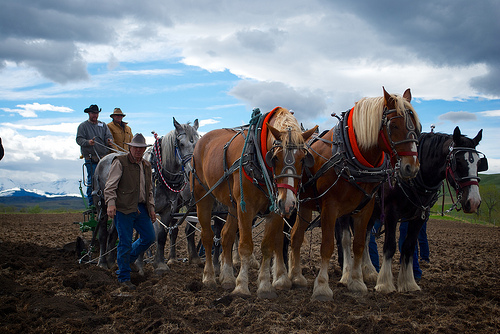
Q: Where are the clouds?
A: Sky.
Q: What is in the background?
A: Hills.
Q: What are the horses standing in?
A: Dirt.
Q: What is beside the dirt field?
A: Grass.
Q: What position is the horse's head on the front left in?
A: Down.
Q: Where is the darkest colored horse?
A: Front right.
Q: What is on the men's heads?
A: Hats.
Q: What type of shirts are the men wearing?
A: Long sleeved.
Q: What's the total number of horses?
A: 4.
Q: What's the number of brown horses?
A: 2.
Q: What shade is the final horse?
A: Grey.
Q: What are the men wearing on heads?
A: Cowboy hats.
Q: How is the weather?
A: Overcast.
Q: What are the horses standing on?
A: Dirt.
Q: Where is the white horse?
A: Closest to the men.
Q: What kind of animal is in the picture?
A: Horses.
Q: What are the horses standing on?
A: A dirt field.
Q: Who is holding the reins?
A: A man.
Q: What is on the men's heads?
A: Hats.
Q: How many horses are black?
A: One.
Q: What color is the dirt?
A: Brown.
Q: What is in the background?
A: Mountains.